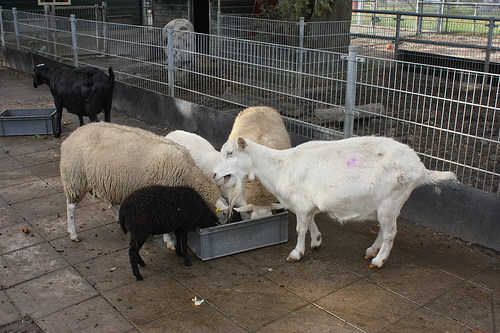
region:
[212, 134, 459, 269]
A white goat with its mouth open.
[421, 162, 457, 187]
Short tail of a white goat with its mouth open.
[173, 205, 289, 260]
A small gray feeding container a bunch of goats are eating out of.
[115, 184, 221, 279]
A small black goat.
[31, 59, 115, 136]
A shiny black goat standing away from other goats.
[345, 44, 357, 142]
A metal fence post behind a white goat.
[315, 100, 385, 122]
A brown log in the fenced area.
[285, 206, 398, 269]
Four white legs on a goat.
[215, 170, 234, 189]
Open mouth of a white goat.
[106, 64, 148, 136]
Black short tail of a goat that's sticking straight up in the air.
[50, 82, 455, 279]
animals are huddled together and eating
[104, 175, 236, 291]
small and black animal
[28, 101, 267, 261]
large grey animal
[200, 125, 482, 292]
white animal is not eating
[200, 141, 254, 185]
mouth is open and eyes are shut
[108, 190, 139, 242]
short black tail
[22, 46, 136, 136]
black animal behind the huddled animals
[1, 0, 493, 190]
metal gate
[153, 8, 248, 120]
animal inside the gate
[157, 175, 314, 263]
silver container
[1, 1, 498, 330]
An indoor photo of farm animals eating.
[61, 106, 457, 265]
Four goats eating food.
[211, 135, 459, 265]
The white goat making a sound.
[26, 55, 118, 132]
A black animal standing.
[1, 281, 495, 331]
A dirty floor underneath.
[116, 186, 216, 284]
A small black baby goat.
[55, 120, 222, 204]
The beige goat eating.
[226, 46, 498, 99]
The metal gate enclosure.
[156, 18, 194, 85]
A spotted cow behind the gate.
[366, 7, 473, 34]
The grassy area outside the area.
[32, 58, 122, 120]
black goat in pen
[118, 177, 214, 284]
black goat in pen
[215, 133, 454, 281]
white goat in pen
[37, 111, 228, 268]
brown goat in pen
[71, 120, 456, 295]
brown, black and white goats in pen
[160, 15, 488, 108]
gray fence of goat pen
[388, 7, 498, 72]
gray fence of goat pen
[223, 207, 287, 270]
gray feeder box in goat pen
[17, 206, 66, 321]
brown tiles in goat pen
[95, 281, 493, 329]
brown tiles in goat pen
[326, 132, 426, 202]
distorted portions of fur on the goat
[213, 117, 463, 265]
adult white goat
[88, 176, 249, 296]
small black animal is eating in the silver container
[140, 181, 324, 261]
silver container that has food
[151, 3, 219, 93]
large animal on the other side of the fence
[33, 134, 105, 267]
sheep's back legs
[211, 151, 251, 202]
goat's mouth is open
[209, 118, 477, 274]
goat is not eating food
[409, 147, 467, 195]
goat's short tail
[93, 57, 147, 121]
black and short tail